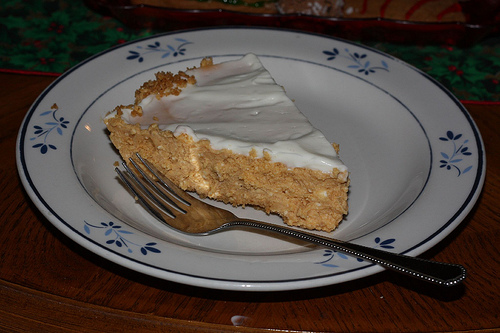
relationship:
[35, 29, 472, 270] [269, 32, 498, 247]
flowers on plate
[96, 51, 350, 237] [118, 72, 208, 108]
pie has a shell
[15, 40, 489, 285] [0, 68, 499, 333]
plate on a table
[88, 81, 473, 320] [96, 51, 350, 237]
fork next to pie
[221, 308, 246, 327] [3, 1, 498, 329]
smudge on table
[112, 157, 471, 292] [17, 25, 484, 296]
fork on plate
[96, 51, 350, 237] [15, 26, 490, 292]
pie on plate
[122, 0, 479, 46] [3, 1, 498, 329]
platter on table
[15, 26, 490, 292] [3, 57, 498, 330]
plate sitting on table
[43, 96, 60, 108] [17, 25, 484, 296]
crumb on plate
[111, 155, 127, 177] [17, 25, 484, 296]
crumb on plate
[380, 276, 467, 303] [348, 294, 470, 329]
shadow on table